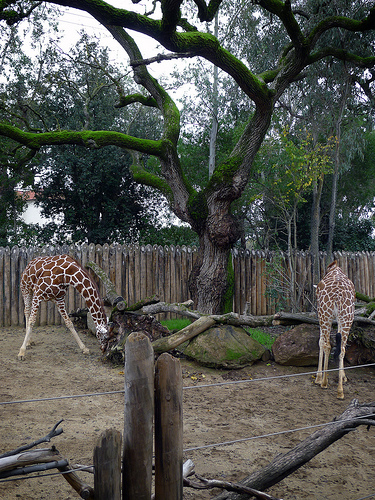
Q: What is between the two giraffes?
A: A tree.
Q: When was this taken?
A: Daytime.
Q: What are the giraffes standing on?
A: Sand.